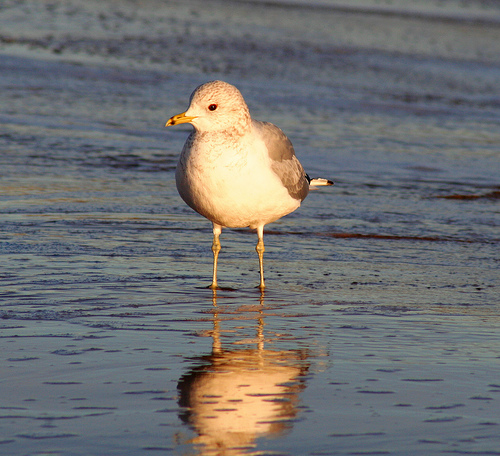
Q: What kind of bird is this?
A: Seagull.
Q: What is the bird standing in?
A: Water.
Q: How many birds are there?
A: One.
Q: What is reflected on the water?
A: The seagull.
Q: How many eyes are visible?
A: One.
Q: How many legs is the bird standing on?
A: Two.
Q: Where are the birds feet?
A: In the water.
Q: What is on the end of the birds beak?
A: Black mark.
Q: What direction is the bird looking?
A: To the left.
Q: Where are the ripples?
A: Water.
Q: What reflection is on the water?
A: Bird.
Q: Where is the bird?
A: Water.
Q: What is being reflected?
A: Bird.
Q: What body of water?
A: Ocean.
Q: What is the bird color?
A: Gray.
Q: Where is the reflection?
A: Water.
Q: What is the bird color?
A: Yellow.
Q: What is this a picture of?
A: A bird.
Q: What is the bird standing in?
A: Water.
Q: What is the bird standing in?
A: Water.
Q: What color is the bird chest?
A: White.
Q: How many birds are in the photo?
A: One.